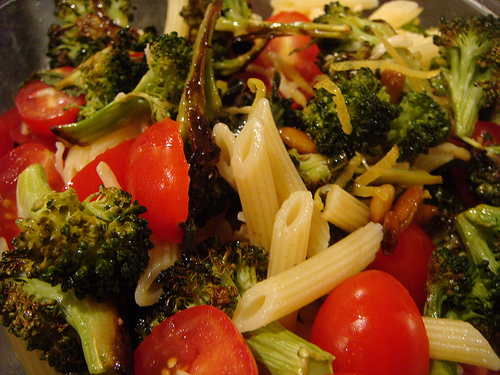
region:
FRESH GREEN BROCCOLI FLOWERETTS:
[35, 221, 125, 292]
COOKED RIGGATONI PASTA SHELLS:
[236, 148, 289, 185]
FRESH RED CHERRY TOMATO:
[340, 300, 407, 374]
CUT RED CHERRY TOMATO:
[22, 87, 46, 131]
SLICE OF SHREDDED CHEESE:
[335, 62, 392, 67]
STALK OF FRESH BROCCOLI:
[263, 335, 297, 365]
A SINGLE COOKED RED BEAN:
[281, 127, 313, 152]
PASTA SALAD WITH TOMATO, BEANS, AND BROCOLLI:
[322, 196, 499, 372]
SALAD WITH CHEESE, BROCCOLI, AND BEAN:
[329, 55, 429, 133]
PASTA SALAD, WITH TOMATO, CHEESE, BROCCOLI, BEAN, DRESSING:
[258, 7, 446, 176]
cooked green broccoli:
[19, 177, 159, 284]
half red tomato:
[133, 294, 271, 371]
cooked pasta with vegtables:
[220, 98, 410, 309]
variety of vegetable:
[10, 10, 495, 357]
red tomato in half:
[285, 253, 495, 366]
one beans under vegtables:
[276, 119, 332, 169]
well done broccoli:
[145, 227, 290, 352]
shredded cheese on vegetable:
[313, 30, 475, 85]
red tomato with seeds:
[130, 302, 238, 372]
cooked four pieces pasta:
[214, 86, 313, 251]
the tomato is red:
[311, 264, 438, 367]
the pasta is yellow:
[233, 92, 334, 316]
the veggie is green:
[19, 202, 165, 373]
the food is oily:
[180, 66, 377, 313]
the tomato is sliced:
[130, 113, 201, 232]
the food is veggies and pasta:
[19, 172, 261, 364]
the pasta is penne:
[222, 75, 344, 316]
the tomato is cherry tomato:
[305, 257, 447, 372]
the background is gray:
[0, 10, 35, 62]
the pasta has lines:
[223, 102, 285, 262]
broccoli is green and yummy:
[10, 165, 135, 363]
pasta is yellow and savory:
[228, 95, 321, 246]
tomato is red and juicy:
[98, 105, 211, 262]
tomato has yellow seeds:
[127, 297, 263, 372]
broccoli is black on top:
[322, 42, 429, 155]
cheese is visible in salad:
[375, 108, 436, 230]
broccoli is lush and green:
[431, 9, 496, 144]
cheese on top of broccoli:
[301, 41, 409, 164]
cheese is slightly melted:
[305, 62, 360, 142]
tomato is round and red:
[303, 246, 460, 361]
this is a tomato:
[360, 285, 400, 350]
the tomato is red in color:
[340, 288, 402, 363]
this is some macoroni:
[273, 246, 311, 296]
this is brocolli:
[43, 195, 126, 290]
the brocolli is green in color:
[84, 240, 134, 280]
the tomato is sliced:
[20, 96, 57, 122]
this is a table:
[5, 0, 36, 66]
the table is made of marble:
[8, 6, 41, 80]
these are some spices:
[363, 17, 429, 112]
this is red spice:
[195, 92, 216, 167]